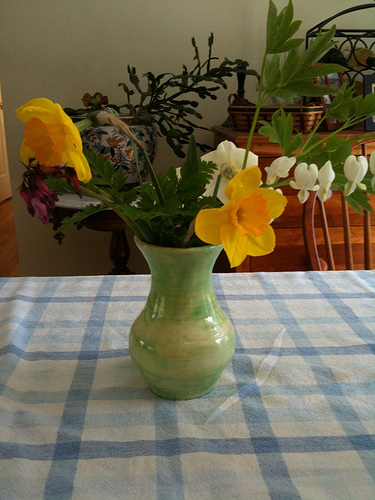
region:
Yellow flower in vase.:
[189, 164, 292, 269]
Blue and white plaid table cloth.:
[1, 268, 374, 499]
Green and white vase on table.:
[126, 230, 236, 399]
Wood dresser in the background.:
[208, 117, 374, 269]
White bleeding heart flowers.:
[244, 133, 372, 205]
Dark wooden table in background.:
[79, 213, 139, 273]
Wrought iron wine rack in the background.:
[303, 1, 373, 110]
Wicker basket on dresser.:
[226, 91, 328, 132]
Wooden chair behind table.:
[299, 175, 374, 273]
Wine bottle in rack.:
[344, 40, 374, 71]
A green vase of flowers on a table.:
[12, 1, 373, 403]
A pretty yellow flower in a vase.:
[193, 164, 291, 268]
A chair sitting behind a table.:
[300, 132, 374, 270]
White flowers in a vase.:
[171, 137, 374, 224]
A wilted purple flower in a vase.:
[20, 156, 84, 227]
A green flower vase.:
[127, 231, 236, 402]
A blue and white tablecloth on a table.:
[1, 271, 373, 499]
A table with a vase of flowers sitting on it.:
[1, 269, 373, 499]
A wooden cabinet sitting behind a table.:
[207, 119, 373, 273]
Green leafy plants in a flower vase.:
[241, 1, 373, 224]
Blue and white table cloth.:
[2, 272, 372, 498]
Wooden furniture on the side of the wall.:
[0, 205, 28, 280]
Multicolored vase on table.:
[68, 93, 149, 199]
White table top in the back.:
[46, 184, 160, 215]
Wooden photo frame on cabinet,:
[306, 59, 355, 131]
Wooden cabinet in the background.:
[210, 114, 374, 270]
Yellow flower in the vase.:
[185, 160, 290, 261]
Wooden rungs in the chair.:
[305, 183, 374, 270]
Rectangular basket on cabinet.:
[226, 93, 326, 138]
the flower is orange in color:
[197, 165, 287, 268]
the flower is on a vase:
[196, 166, 288, 266]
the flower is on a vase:
[200, 142, 260, 205]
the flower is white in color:
[196, 143, 259, 203]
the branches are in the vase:
[235, 1, 371, 208]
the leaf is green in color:
[261, 111, 299, 156]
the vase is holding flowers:
[128, 233, 235, 402]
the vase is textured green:
[132, 235, 230, 399]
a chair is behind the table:
[306, 168, 372, 271]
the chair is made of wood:
[305, 173, 373, 271]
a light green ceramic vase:
[128, 227, 235, 397]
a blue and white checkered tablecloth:
[1, 273, 373, 498]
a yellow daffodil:
[196, 163, 283, 263]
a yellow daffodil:
[13, 95, 91, 180]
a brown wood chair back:
[300, 191, 374, 266]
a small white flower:
[202, 138, 258, 198]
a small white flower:
[260, 150, 296, 184]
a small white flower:
[289, 160, 316, 201]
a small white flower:
[314, 159, 335, 201]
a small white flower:
[341, 151, 365, 198]